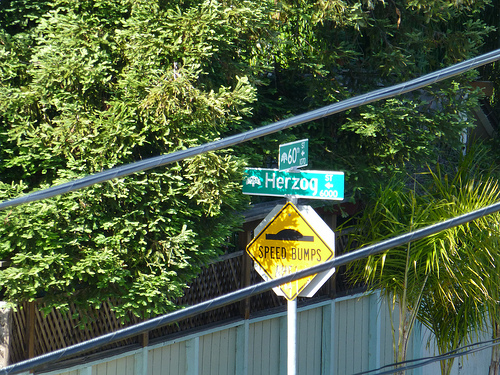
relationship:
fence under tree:
[71, 280, 178, 340] [90, 199, 175, 334]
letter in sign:
[300, 178, 308, 190] [241, 135, 346, 301]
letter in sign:
[266, 172, 276, 188] [251, 203, 336, 297]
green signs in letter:
[238, 165, 345, 202] [273, 172, 284, 189]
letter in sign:
[262, 168, 274, 193] [239, 161, 347, 203]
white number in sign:
[287, 145, 293, 165] [269, 137, 310, 167]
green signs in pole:
[237, 131, 348, 205] [282, 190, 301, 373]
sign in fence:
[278, 138, 309, 170] [373, 260, 500, 375]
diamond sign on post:
[246, 202, 334, 302] [275, 298, 308, 353]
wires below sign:
[9, 44, 472, 369] [245, 201, 347, 371]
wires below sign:
[9, 44, 472, 369] [239, 170, 349, 198]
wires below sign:
[9, 44, 472, 369] [276, 136, 311, 172]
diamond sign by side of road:
[246, 202, 334, 302] [195, 342, 483, 372]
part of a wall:
[210, 348, 253, 370] [34, 284, 499, 374]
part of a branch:
[115, 226, 181, 270] [130, 215, 170, 273]